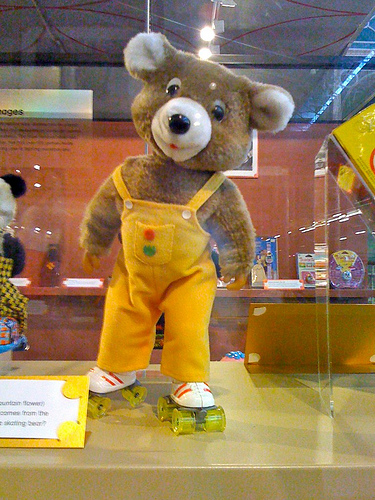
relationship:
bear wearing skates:
[89, 33, 294, 408] [88, 386, 224, 435]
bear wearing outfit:
[89, 33, 294, 408] [97, 168, 228, 384]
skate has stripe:
[157, 379, 225, 437] [179, 387, 193, 399]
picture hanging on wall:
[224, 129, 262, 178] [0, 121, 340, 282]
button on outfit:
[126, 200, 134, 209] [97, 168, 228, 384]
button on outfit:
[183, 209, 193, 219] [97, 168, 228, 384]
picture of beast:
[254, 234, 281, 281] [254, 249, 276, 286]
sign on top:
[63, 276, 103, 288] [18, 277, 110, 294]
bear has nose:
[89, 33, 294, 408] [170, 116, 191, 132]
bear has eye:
[89, 33, 294, 408] [169, 77, 182, 95]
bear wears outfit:
[89, 33, 294, 408] [97, 168, 228, 384]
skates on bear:
[88, 386, 224, 435] [89, 33, 294, 408]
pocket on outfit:
[134, 221, 176, 263] [97, 168, 228, 384]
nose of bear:
[170, 116, 191, 132] [89, 33, 294, 408]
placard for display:
[0, 374, 90, 448] [0, 30, 375, 499]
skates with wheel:
[88, 386, 224, 435] [173, 409, 194, 433]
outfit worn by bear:
[97, 168, 228, 384] [89, 33, 294, 408]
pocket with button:
[134, 221, 176, 263] [146, 230, 155, 243]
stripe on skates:
[179, 387, 193, 399] [88, 386, 224, 435]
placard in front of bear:
[0, 374, 90, 448] [89, 33, 294, 408]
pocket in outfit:
[134, 221, 176, 263] [97, 168, 228, 384]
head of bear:
[124, 32, 297, 171] [89, 33, 294, 408]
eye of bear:
[169, 77, 182, 95] [89, 33, 294, 408]